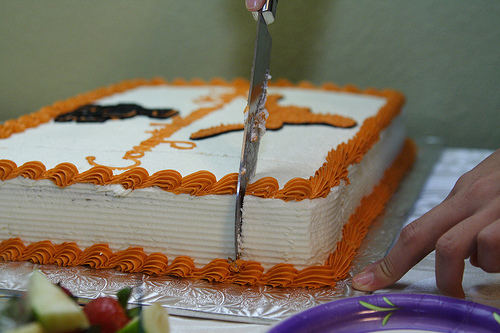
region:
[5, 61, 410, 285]
an orange and white frosted sheet cake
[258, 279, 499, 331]
a purple paper plate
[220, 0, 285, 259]
a silver cake knife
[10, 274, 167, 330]
a bowl of fruit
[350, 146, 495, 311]
a person's hand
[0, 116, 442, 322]
a silver cake tray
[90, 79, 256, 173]
handwriting in cake frosting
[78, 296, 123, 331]
a red strawberry fruit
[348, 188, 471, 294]
a person's middle finger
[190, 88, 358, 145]
an orange corporate logo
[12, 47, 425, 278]
a cake on a tray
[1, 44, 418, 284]
the cake is decorated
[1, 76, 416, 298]
the cake is white with orange trim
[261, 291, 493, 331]
the plate on the table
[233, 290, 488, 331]
the plate is purple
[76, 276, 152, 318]
the strawberry on the table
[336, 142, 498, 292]
the hand holding the tray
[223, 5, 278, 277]
the knife cutting into the cake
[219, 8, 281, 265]
the knife is metal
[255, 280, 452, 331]
the plate is paper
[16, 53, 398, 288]
White and orange cake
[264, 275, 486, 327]
A round purple plate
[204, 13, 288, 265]
Knife cutting into cake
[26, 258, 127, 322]
Fruit next to the cake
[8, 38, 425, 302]
The cake has an orange border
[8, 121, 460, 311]
Cake is on a silver platter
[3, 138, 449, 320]
The platter is shiny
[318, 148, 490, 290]
The person is holding the platter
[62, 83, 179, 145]
Black image on top of cake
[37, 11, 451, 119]
The wall is green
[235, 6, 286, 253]
silver knife with icing on it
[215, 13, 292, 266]
knife cutting through cake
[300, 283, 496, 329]
purple paper plate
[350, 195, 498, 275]
a person's finger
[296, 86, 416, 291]
orange and white icing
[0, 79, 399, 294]
orange and white icing on a cake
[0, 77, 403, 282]
rectangular cake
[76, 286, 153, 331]
pink strawberry with green leaf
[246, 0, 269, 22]
finger on handle of a knife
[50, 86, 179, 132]
black icing on cake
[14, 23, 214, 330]
a cake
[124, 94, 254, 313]
a cake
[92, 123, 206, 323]
a cake